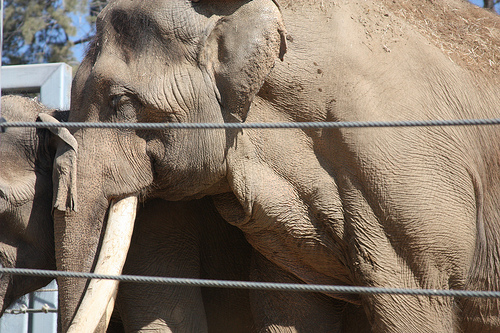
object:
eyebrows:
[99, 76, 131, 86]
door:
[0, 58, 74, 333]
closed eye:
[105, 93, 124, 110]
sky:
[2, 2, 97, 64]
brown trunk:
[49, 130, 155, 333]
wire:
[1, 266, 498, 298]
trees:
[0, 0, 94, 64]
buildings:
[0, 58, 90, 330]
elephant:
[48, 0, 500, 333]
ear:
[204, 0, 290, 128]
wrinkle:
[149, 60, 195, 105]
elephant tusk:
[63, 193, 140, 333]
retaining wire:
[1, 118, 497, 129]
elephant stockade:
[0, 117, 500, 333]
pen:
[1, 0, 498, 331]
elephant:
[0, 89, 81, 314]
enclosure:
[0, 0, 496, 325]